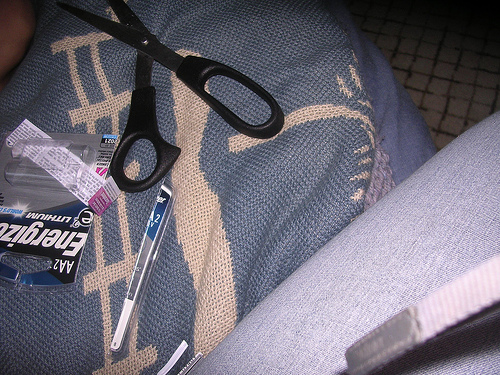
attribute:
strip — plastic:
[101, 172, 181, 364]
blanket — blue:
[12, 7, 384, 356]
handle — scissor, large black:
[101, 43, 286, 199]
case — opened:
[85, 185, 193, 350]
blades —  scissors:
[41, 0, 141, 39]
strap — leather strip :
[133, 66, 163, 180]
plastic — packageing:
[15, 119, 87, 272]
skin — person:
[2, 5, 54, 65]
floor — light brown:
[392, 10, 482, 99]